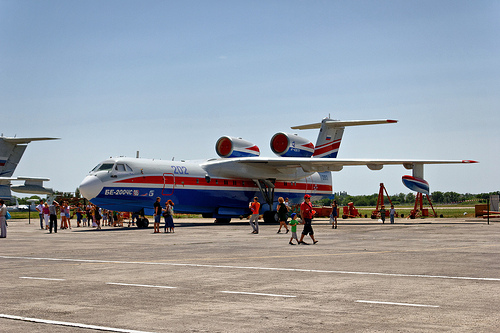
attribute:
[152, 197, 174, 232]
group — in the picture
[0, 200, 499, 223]
grass — in the picture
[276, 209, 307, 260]
dress — green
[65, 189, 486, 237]
people — standing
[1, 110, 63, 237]
airplane — grey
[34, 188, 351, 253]
some peopel — in the picture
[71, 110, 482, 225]
airplane — gray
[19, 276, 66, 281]
marking strip — white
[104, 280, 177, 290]
marking strip — white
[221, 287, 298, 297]
marking strip — white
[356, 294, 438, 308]
marking strip — white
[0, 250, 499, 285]
marking strip — white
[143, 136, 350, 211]
colors — red, white, blue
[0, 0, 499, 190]
sky — in the picture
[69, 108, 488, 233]
plane — red, white, blue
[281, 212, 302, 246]
child — in the picture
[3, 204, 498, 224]
fields — grass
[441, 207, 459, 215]
grass — in the picture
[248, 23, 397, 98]
sky — blue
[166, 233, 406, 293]
lines — white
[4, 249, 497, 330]
line — white